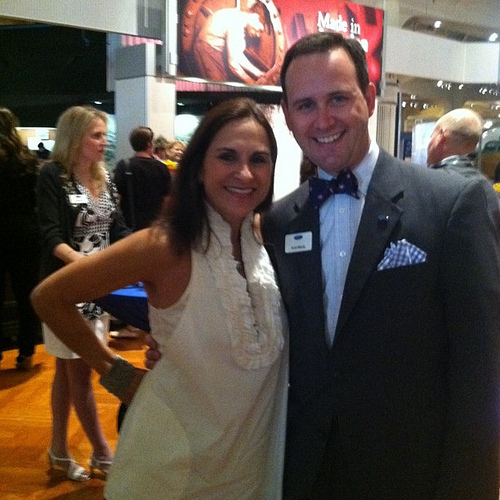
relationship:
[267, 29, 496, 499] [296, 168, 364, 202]
man wearing bowtie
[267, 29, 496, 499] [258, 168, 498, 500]
man wearing suit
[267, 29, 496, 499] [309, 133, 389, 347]
man wearing shirt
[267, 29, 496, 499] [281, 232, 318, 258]
man wearing nametag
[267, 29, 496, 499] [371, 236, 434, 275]
man wearing pocket square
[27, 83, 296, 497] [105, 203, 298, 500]
woman wearing white top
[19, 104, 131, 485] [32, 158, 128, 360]
woman wearing dress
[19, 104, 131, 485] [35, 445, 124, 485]
woman wearing sandles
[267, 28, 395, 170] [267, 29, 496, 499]
head of man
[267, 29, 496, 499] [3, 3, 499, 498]
man posing photo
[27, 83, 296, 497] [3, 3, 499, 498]
woman posing photo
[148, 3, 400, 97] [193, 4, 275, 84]
sign has figure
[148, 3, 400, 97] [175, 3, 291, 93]
sign has wheel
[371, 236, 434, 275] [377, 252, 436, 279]
handkerchief in lapelle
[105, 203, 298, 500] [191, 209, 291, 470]
coctail dress has front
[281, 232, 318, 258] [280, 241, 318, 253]
nametag has writing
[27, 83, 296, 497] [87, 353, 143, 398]
woman has bracelet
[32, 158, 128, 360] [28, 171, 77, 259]
cardigan has sleeves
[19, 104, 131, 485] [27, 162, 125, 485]
woman wearing black and white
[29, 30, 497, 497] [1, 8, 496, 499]
couple at event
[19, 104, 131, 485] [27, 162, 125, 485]
woman wears outfit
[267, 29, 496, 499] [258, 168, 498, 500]
man has suit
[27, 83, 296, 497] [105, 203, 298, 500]
woman wearing dress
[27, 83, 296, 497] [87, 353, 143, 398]
woman wearing bracelet